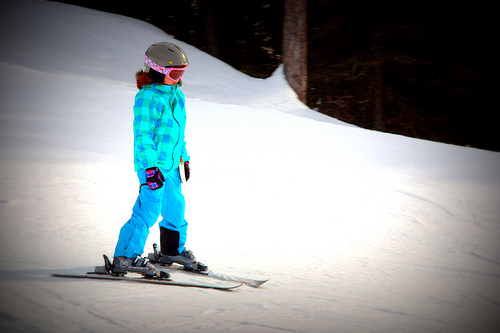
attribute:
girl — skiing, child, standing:
[51, 36, 267, 304]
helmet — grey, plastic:
[130, 36, 194, 76]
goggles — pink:
[142, 58, 183, 80]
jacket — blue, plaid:
[132, 82, 196, 166]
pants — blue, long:
[125, 167, 196, 252]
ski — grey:
[53, 266, 235, 294]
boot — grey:
[113, 250, 146, 266]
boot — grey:
[161, 222, 192, 255]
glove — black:
[145, 165, 170, 190]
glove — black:
[182, 153, 197, 180]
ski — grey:
[168, 255, 270, 288]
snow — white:
[3, 35, 473, 333]